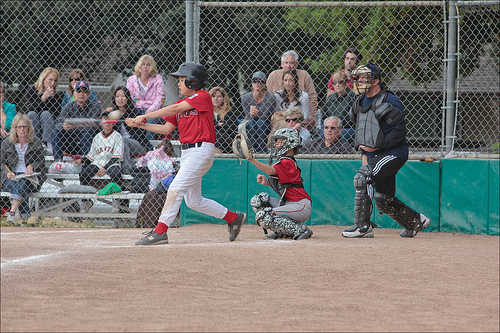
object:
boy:
[120, 56, 251, 253]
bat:
[60, 105, 152, 141]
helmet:
[166, 54, 216, 99]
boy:
[247, 126, 317, 243]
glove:
[229, 121, 260, 171]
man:
[338, 45, 437, 247]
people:
[0, 38, 412, 166]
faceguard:
[345, 58, 388, 104]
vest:
[349, 85, 397, 157]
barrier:
[180, 157, 500, 236]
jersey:
[159, 88, 222, 154]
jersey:
[268, 153, 316, 205]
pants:
[152, 137, 234, 232]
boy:
[70, 105, 134, 225]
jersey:
[84, 126, 127, 169]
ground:
[0, 222, 499, 332]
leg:
[148, 147, 206, 242]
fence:
[1, 1, 499, 230]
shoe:
[131, 225, 176, 250]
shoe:
[224, 200, 253, 248]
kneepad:
[350, 159, 378, 197]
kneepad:
[370, 183, 404, 219]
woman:
[235, 64, 279, 154]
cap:
[248, 66, 271, 95]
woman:
[1, 108, 52, 232]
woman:
[19, 61, 70, 162]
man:
[49, 75, 110, 162]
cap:
[67, 75, 94, 102]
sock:
[217, 201, 242, 228]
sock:
[150, 211, 175, 239]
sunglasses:
[72, 85, 92, 96]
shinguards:
[389, 201, 430, 235]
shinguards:
[348, 188, 379, 241]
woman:
[119, 42, 170, 142]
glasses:
[11, 121, 32, 133]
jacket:
[121, 71, 168, 113]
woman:
[202, 82, 241, 160]